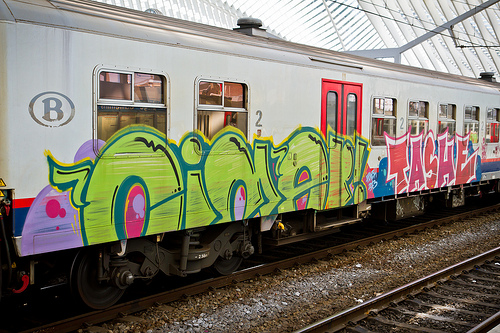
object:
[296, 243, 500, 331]
rail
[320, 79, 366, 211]
door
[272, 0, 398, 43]
wall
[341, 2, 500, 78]
wires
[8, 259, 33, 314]
machinery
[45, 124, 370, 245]
caligraphy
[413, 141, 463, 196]
ground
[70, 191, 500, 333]
ground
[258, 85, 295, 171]
wall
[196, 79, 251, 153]
window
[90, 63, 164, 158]
window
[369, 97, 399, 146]
window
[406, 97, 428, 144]
window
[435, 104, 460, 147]
window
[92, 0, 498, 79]
ceiling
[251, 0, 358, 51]
light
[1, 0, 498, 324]
train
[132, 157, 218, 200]
wall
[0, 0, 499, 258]
side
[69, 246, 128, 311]
wheel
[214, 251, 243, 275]
wheel